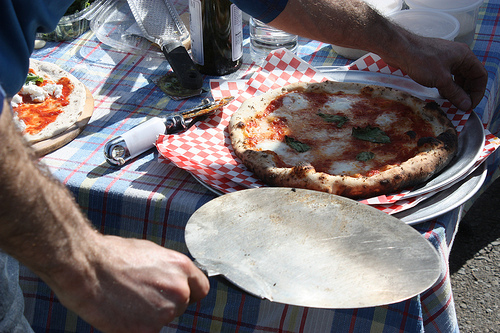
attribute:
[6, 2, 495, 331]
tablecloth — blue, plaid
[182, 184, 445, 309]
tray — round, metal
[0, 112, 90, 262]
arm — hairy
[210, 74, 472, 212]
pizza — big 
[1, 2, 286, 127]
shirt — blue 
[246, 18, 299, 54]
water glass — clear 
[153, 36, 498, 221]
paper — red, white, checkered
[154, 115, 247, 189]
paper — white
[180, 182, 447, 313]
pan — empty, metal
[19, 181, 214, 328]
hand — hairy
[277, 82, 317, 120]
cheese — melted 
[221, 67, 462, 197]
pizza — unsliced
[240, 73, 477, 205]
pizza — red 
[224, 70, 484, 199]
pan — round 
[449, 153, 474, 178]
pizza tray — round 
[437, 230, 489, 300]
wall — concrete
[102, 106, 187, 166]
handle — white 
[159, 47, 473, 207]
paper — red, white, checkered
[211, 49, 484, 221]
paper — red, white, checkered